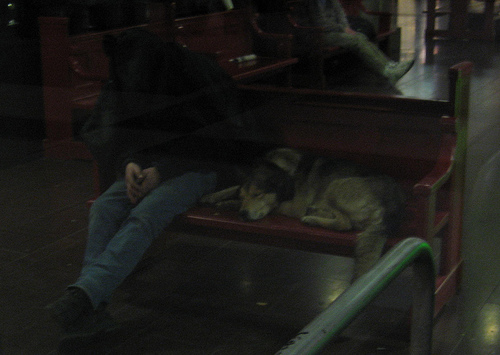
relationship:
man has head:
[44, 27, 272, 333] [105, 26, 189, 122]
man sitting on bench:
[44, 27, 272, 333] [93, 76, 475, 311]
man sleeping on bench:
[44, 27, 272, 333] [93, 76, 475, 311]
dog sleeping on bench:
[199, 147, 412, 288] [63, 70, 471, 339]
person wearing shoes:
[311, 4, 416, 89] [388, 60, 418, 86]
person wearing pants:
[299, 0, 415, 89] [317, 29, 428, 89]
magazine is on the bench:
[217, 43, 265, 73] [140, 8, 421, 86]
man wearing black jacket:
[44, 27, 272, 333] [76, 23, 271, 198]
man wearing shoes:
[44, 27, 272, 333] [48, 285, 128, 347]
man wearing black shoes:
[44, 27, 272, 333] [33, 287, 75, 322]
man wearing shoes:
[44, 27, 272, 333] [27, 272, 127, 350]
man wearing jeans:
[44, 27, 272, 333] [68, 175, 211, 293]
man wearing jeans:
[44, 27, 272, 333] [64, 156, 216, 315]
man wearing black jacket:
[45, 30, 272, 316] [70, 28, 269, 198]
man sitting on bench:
[45, 30, 272, 316] [93, 76, 475, 311]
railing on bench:
[271, 239, 445, 350] [83, 57, 484, 340]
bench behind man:
[35, 4, 305, 161] [44, 27, 272, 333]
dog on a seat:
[199, 147, 412, 288] [150, 60, 472, 320]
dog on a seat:
[199, 147, 412, 288] [82, 60, 475, 321]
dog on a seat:
[186, 146, 411, 241] [82, 60, 475, 321]